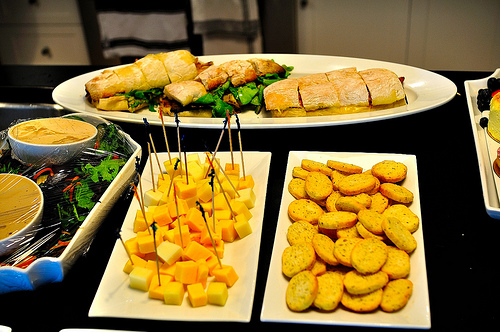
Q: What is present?
A: Food.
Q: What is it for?
A: Eating.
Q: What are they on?
A: A table.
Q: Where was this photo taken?
A: In a kitchen.